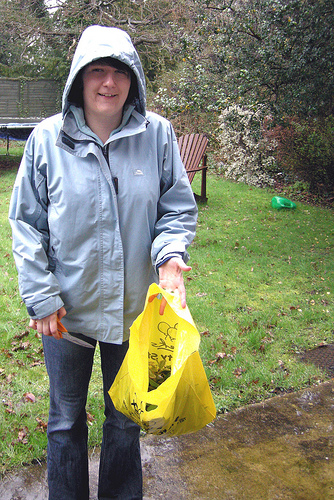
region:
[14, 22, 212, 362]
person in a blue coat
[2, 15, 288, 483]
person standing in the rain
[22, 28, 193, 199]
person with their hood on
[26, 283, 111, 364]
pair of orange handled scissors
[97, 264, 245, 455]
a yellow plastic bag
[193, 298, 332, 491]
a wet sidewalk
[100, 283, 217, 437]
A yellow plastic bag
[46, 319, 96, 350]
Orange handled scissors in a hand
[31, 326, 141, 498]
Blue jeans on a person's legs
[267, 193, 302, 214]
A green container in the grass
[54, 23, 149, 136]
A hood on a gray hoodie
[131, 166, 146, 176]
A white decal on a jacket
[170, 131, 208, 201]
A chair with brown slats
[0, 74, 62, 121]
A wooden fence in a yard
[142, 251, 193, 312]
A hand holding a bag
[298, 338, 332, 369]
Metal cover in the grass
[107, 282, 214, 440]
A yellow bag in a person's hand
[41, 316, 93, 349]
Orange handled scissors in a girl's hand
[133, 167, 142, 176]
White label on a jacket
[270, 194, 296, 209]
Green plastic container on grass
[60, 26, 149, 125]
Gray hood on a jacket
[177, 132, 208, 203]
A brown adirondak chair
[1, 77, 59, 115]
A tall fence around a yard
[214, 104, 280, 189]
A bush filled with flowers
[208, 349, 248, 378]
Dead leaves on grass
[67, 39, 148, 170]
a woman wearing a jacket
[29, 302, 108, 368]
a woman holding scisors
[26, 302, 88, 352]
scissors with orange handle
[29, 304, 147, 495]
a woman wearing jeans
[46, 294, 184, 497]
a woman wearing blue jeans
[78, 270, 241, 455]
a woman holding a bag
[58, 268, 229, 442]
a woman holding yellow bag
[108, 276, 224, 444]
an open yellow bag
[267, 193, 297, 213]
A green watering can sitting in the grass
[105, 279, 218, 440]
A plastic yellow bag containing leaves and debris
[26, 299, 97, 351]
A hand holding a pair of scissors with orange grips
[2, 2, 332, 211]
A grove of trees and bushes in the back of the yard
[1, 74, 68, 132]
A privacy fence with vines growing on it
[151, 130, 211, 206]
An outdoor lounging chair made of wood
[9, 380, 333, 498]
Cement walkway wet from rain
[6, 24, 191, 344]
Person wearing a blue jacket with the hood up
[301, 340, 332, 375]
The left side of a storm drain in the grass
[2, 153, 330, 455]
Grass littered with leaves and twigs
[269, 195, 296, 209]
green container on the grass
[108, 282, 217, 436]
a yellow plastic bag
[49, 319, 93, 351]
a pair of orange scissors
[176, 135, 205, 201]
part of wooden chair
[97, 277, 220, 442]
yellow plastic shopping bag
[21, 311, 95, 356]
scissors with orange handle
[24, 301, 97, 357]
hand holding pair of scissors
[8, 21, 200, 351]
light blue hooded jacket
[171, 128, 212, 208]
wooden adirondack style chair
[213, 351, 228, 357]
A leaf on the ground.